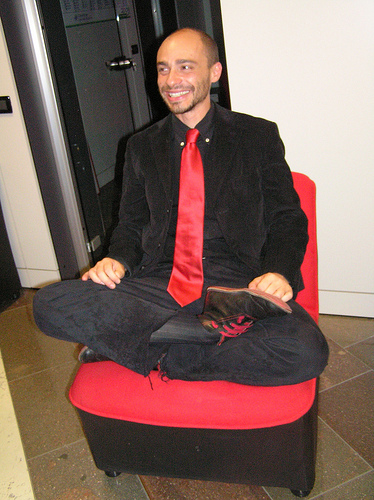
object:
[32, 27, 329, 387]
man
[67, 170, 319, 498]
chair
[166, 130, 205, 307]
tie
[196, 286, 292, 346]
shoe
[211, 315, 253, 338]
shoelaces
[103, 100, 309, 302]
jacket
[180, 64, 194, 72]
eyes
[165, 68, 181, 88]
nose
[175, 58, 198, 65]
eyebrows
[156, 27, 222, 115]
head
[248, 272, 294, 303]
left hand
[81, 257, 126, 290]
right hand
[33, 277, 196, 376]
legs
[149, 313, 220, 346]
sock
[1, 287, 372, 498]
floor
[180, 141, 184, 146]
buttons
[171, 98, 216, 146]
collar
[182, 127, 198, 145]
knot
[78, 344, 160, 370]
shoe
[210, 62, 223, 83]
ear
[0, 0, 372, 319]
wall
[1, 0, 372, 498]
room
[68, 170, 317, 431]
cushion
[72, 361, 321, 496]
base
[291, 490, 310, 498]
front foot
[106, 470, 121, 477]
front foot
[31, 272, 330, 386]
pants